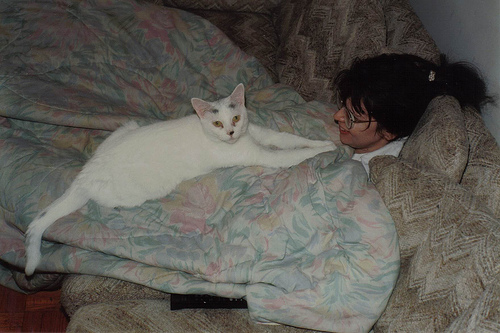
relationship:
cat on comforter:
[21, 77, 341, 278] [2, 3, 402, 330]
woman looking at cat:
[325, 50, 488, 166] [21, 77, 341, 278]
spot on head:
[222, 100, 240, 109] [186, 81, 250, 147]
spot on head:
[205, 104, 220, 114] [186, 81, 250, 147]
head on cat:
[186, 81, 250, 147] [21, 276, 338, 305]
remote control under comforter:
[167, 289, 247, 310] [2, 3, 402, 330]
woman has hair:
[325, 50, 487, 175] [328, 51, 498, 141]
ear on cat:
[226, 79, 247, 109] [21, 77, 341, 278]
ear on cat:
[183, 95, 211, 119] [21, 77, 341, 278]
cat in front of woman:
[21, 77, 341, 278] [325, 50, 487, 175]